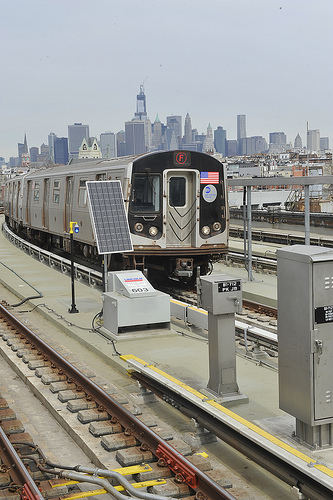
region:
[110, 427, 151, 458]
the railroad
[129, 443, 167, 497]
the railroad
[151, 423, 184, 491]
the railroad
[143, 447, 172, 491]
the railroad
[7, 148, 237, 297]
a commuter train on the tracks outside a large city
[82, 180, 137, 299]
a rectangular solar panel used to power the train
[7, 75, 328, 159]
a cityscape woth many tall buildings in the distance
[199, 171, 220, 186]
a small American flag on the end of the train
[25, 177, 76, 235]
three doors and two windows on the train car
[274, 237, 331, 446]
a grey electrical box next to the tracks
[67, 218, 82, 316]
a small thin pole with a blue light at the top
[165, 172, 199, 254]
a door with a window at the end of the train car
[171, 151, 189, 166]
a red F in a red circle on the top of the train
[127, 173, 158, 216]
a small window next to a door at the end of the train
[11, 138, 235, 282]
the train is on the tracks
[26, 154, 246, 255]
the train car is brown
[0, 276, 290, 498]
multiple tracks are present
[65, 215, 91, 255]
a blue light hangs by the side of the track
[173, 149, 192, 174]
a red F is on the train car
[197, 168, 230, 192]
an american flag is on the train car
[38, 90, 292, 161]
many skyscrapers dot the background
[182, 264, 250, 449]
grey mechanical boxes are by the tracks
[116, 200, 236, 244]
the train has 4 lights on it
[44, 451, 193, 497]
silver hose type things snake across the vacant track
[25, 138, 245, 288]
commuter train on tracks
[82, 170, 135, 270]
rectangle solar panel on pole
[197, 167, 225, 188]
american flag on train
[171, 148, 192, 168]
red letter in circle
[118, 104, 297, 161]
city skyline on horizon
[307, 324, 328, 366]
handle on gray box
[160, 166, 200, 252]
door with window on train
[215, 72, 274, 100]
blue of daytime sky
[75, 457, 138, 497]
two curved metal poles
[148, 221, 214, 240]
lights on black surface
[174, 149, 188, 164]
The letter 'F' illuminated red in a circle.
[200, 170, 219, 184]
American flag on front of train.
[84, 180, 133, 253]
Solar panel on train station platform.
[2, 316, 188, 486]
metal train tracks.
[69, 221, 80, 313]
Black and yellow light pole.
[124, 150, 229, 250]
Front of train.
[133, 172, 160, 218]
Window for conductor.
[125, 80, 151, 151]
Tall city building in background.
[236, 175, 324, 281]
Metal fence railing at station.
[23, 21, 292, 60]
Blue, sky clear of clouds and hazy.